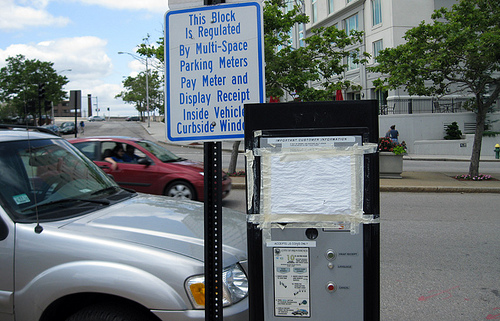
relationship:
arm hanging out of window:
[105, 156, 117, 169] [102, 142, 154, 165]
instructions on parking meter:
[272, 246, 314, 319] [241, 104, 376, 319]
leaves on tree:
[1, 53, 70, 113] [1, 53, 71, 124]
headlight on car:
[221, 260, 248, 309] [1, 127, 247, 317]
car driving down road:
[35, 136, 231, 201] [56, 115, 498, 320]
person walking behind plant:
[387, 125, 398, 138] [382, 140, 407, 170]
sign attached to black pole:
[163, 1, 265, 145] [198, 141, 227, 310]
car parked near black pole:
[1, 127, 247, 317] [202, 142, 224, 320]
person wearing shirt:
[102, 144, 126, 171] [99, 140, 150, 160]